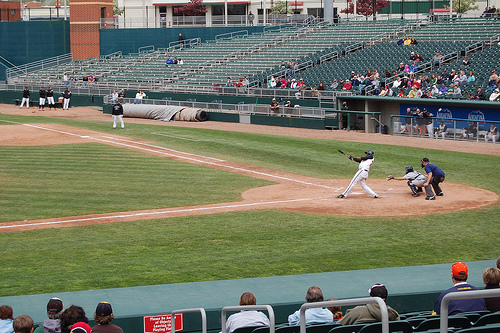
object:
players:
[20, 86, 31, 108]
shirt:
[404, 172, 425, 185]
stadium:
[2, 0, 499, 333]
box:
[335, 173, 378, 199]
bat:
[337, 149, 350, 159]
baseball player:
[337, 149, 380, 198]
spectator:
[289, 286, 332, 324]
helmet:
[364, 150, 374, 156]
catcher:
[385, 165, 429, 197]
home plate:
[349, 184, 369, 199]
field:
[0, 102, 497, 303]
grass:
[195, 233, 318, 272]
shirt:
[222, 310, 272, 333]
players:
[478, 132, 487, 139]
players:
[465, 122, 479, 135]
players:
[434, 127, 440, 134]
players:
[423, 114, 433, 125]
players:
[395, 125, 406, 134]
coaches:
[405, 107, 414, 136]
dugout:
[362, 101, 500, 147]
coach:
[412, 107, 425, 138]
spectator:
[419, 157, 445, 201]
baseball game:
[2, 0, 499, 330]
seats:
[299, 59, 339, 79]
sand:
[297, 198, 383, 218]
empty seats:
[224, 18, 500, 36]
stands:
[3, 10, 498, 103]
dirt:
[266, 191, 302, 194]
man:
[222, 288, 273, 333]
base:
[81, 127, 101, 149]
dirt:
[269, 182, 305, 203]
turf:
[82, 156, 191, 211]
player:
[487, 124, 494, 139]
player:
[467, 125, 478, 141]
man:
[431, 259, 486, 320]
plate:
[350, 192, 364, 195]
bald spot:
[309, 288, 317, 295]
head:
[303, 285, 323, 303]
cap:
[451, 261, 471, 276]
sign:
[142, 311, 184, 331]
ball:
[385, 175, 393, 183]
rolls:
[112, 102, 207, 122]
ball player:
[111, 100, 124, 129]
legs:
[341, 169, 366, 197]